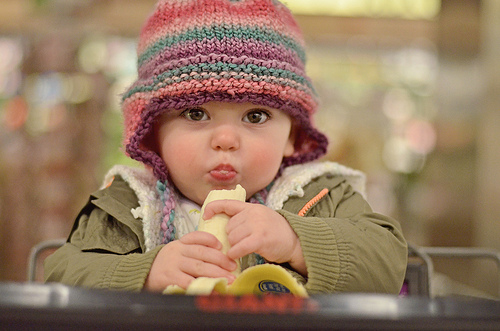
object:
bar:
[0, 276, 498, 328]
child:
[33, 0, 435, 293]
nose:
[210, 123, 240, 151]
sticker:
[256, 278, 289, 294]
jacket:
[44, 169, 409, 294]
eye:
[239, 107, 273, 124]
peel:
[163, 262, 317, 295]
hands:
[197, 198, 295, 263]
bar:
[414, 246, 500, 261]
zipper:
[298, 186, 328, 217]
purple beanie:
[123, 0, 327, 179]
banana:
[166, 184, 312, 300]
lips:
[209, 161, 238, 171]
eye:
[176, 106, 212, 123]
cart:
[0, 233, 500, 329]